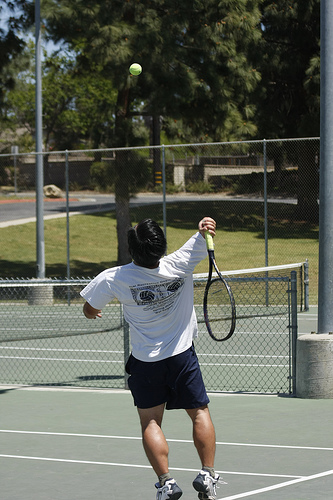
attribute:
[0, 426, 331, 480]
lines — white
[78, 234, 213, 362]
shirt — white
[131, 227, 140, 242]
hair — man's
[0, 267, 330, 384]
fence — high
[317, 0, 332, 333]
pole — grey, cement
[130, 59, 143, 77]
tennis ball — yellow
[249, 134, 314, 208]
fence — metal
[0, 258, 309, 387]
net — black, white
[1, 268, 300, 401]
fence — grey, chain link, chain-link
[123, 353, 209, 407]
shorts — black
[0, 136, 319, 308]
fence — tall, chain link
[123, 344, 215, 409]
shorts — dark blue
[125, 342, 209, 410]
shorts — navy blue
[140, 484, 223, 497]
tennis shoes — black, white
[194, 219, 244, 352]
racket — black, white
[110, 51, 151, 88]
ball — yellow , tennis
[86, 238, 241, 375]
shirt — white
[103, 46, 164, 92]
ball — yellow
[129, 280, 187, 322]
writing — black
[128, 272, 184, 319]
print — black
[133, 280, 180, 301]
image — black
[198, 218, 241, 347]
racket — tennis